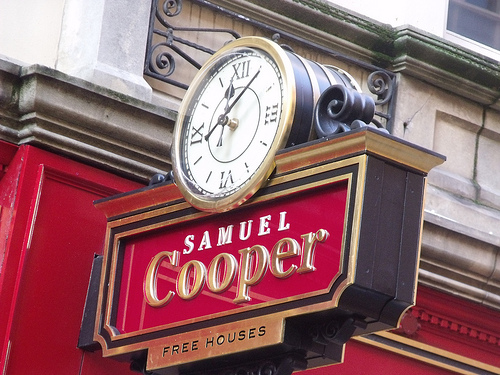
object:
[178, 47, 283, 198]
face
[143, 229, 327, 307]
word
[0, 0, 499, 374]
building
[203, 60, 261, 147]
time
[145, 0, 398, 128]
iron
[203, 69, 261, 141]
hand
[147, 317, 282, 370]
sign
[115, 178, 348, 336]
sign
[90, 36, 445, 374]
sign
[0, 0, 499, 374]
wall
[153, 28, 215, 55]
bars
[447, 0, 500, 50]
window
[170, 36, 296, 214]
clock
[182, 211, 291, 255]
word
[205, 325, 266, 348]
word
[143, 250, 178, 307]
c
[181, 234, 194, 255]
s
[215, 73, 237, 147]
hand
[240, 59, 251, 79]
numbers